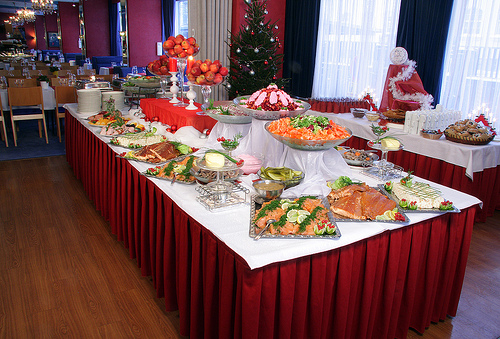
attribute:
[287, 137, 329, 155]
bowl — at table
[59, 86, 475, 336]
table — at table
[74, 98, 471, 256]
tablecloth — white 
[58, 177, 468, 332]
tablecloth — red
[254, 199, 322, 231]
food — at table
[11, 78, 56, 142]
chair — woody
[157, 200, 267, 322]
tablecloth — red 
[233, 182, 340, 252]
tray — at table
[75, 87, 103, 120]
plates — white 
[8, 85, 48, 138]
chair — at table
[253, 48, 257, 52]
ornaments — white 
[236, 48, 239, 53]
ornaments — red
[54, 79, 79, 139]
chair — empty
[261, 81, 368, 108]
wall — brown 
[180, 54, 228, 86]
fruit — at table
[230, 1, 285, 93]
wall — red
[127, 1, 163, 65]
wall — red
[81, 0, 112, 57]
wall — red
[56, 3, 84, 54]
wall — red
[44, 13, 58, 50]
wall — red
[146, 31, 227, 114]
bowls — display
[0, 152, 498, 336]
wooden floor — brown 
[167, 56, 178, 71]
candle — red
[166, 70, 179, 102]
candlestick — white 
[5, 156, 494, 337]
carpet — blue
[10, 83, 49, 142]
chair — wooden 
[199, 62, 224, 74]
fruit — whole